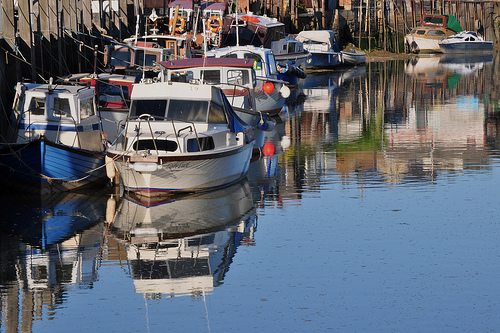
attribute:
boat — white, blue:
[5, 78, 110, 193]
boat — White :
[93, 57, 315, 248]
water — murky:
[12, 55, 497, 327]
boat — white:
[69, 29, 306, 199]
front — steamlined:
[108, 141, 227, 199]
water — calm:
[362, 210, 410, 273]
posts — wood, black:
[2, 4, 129, 64]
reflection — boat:
[105, 185, 256, 299]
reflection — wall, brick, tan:
[432, 103, 488, 146]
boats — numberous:
[12, 35, 350, 196]